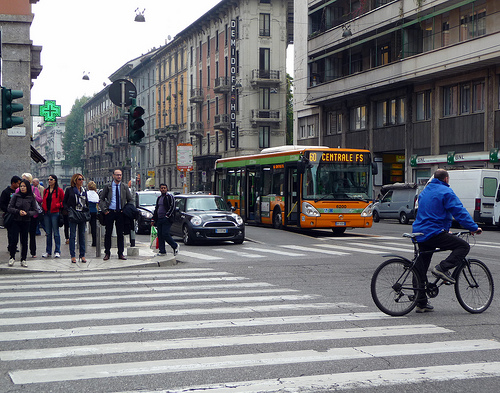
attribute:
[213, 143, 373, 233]
bus — orange, green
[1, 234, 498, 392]
lines — white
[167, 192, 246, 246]
car — black, stopped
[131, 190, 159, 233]
car — stopped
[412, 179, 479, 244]
jacket — blue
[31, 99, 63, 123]
sign — green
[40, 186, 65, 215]
jacket — red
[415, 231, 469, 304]
pants — black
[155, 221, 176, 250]
pants — black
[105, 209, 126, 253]
pants — black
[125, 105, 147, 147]
traffic light — dark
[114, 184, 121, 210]
tie — blue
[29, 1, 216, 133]
sky — cloudy, gray